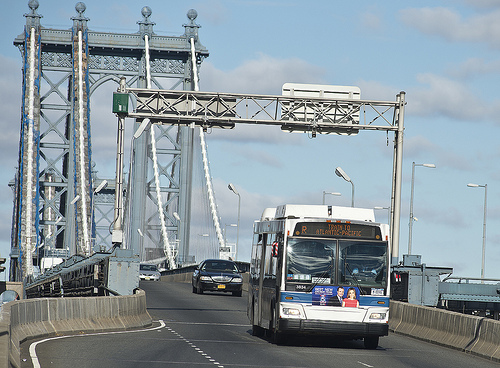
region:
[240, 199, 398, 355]
bus on a street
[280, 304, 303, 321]
front headlight on a bus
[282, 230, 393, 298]
front windshield on a bus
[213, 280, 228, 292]
front licence plate on a vehicle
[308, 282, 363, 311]
advertising sign on a bus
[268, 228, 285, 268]
side rear view mirror on a bus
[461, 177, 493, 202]
street light on a pole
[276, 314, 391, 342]
black bumper on a bus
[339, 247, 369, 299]
windshield wiper on a bus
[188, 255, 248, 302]
car on a street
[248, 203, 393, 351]
A white and blue bus.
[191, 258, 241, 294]
A black car with an orange license plate.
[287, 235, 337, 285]
Front left windshield of a bus.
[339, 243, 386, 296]
Front right windshield of a bus.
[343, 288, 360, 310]
A woman on the front of a bus in a pink top.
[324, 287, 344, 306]
A man in a black suit on the front of a bus.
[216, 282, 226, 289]
Orange license plate on the front of a black car.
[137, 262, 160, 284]
A silver car coming across a bridge.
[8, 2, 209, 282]
Four very tall pillars with round balls on the top.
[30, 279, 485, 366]
Paved black road cars are driving on.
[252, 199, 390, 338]
blue and white bus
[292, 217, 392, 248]
destination bus is going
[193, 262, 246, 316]
dark car following bus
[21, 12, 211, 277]
large steel bridge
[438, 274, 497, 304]
walkway over the bridge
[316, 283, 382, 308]
advertisment on front of bus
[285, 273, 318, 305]
number of the bus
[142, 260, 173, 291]
light colored car driving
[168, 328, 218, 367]
white markings in the road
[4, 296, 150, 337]
concrete divider on the road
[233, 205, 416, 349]
bus on the road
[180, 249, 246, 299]
car on the road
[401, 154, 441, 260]
light on the top of the pole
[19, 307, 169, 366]
white line is curved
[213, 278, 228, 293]
yellow license plate on the front of the car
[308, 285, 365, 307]
advertisement on the front of the bus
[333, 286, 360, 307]
picture of a man and a woman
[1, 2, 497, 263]
clouds in the pale blue sky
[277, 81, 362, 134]
back of a sign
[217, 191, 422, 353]
bus on a bridge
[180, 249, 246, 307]
black car driving on a road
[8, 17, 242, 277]
bridge made of steel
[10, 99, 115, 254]
cables holding bridge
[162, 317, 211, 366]
white lines on road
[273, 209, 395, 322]
the bus has a windshield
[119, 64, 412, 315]
the signs are on a pole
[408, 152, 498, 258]
lights on light poles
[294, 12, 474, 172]
few clouds in the blue sky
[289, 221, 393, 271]
neon sign on the bus